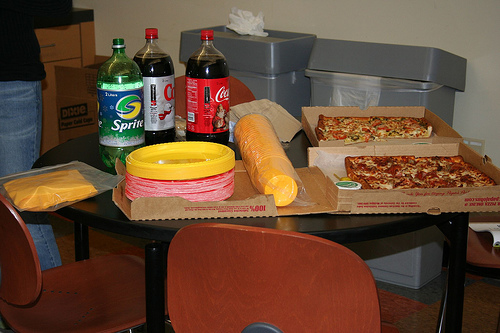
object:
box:
[297, 106, 462, 147]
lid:
[126, 141, 236, 182]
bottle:
[132, 23, 177, 143]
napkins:
[2, 169, 99, 212]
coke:
[185, 25, 251, 167]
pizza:
[344, 154, 496, 195]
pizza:
[315, 113, 432, 140]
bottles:
[94, 38, 145, 169]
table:
[32, 102, 485, 333]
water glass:
[233, 110, 297, 206]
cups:
[233, 112, 298, 207]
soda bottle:
[135, 47, 177, 145]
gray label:
[144, 77, 174, 132]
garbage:
[178, 15, 317, 79]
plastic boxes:
[308, 34, 466, 288]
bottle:
[187, 28, 229, 145]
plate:
[125, 141, 236, 181]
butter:
[334, 181, 359, 190]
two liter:
[96, 36, 144, 166]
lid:
[144, 25, 160, 41]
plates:
[125, 139, 238, 202]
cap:
[200, 27, 215, 39]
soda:
[185, 52, 229, 143]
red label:
[183, 76, 233, 136]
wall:
[102, 0, 499, 168]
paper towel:
[466, 221, 500, 247]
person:
[0, 1, 93, 271]